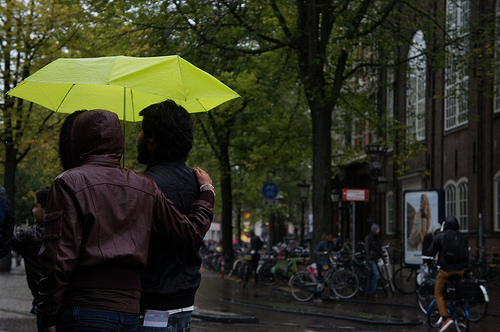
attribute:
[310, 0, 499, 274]
building — dark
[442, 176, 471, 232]
windows — white-paned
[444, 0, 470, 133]
windows — white-paned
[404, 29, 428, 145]
windows — white-paned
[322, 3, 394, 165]
windows — white-paned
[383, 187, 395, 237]
windows — white-paned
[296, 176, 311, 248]
pole — black, light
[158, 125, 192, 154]
hair — short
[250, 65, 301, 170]
leaves — green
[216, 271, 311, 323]
street — wet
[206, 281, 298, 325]
road — wet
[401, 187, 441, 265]
board — advertisement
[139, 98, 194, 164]
hair — black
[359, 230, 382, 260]
coat — dark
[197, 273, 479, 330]
road — wet, dark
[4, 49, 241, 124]
umbrella — yellow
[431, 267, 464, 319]
pants — tan